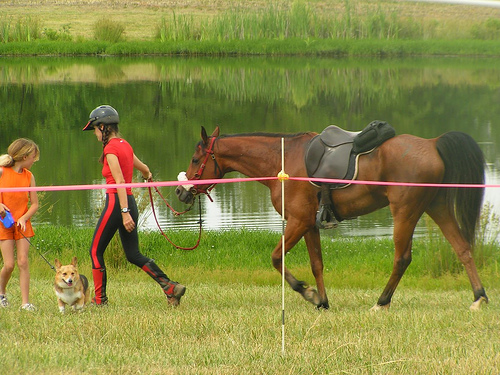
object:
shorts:
[0, 205, 36, 240]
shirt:
[99, 133, 136, 193]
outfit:
[0, 161, 37, 241]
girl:
[78, 100, 188, 305]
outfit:
[86, 137, 187, 308]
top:
[104, 134, 139, 193]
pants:
[90, 192, 171, 279]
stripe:
[85, 267, 103, 302]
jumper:
[1, 167, 35, 244]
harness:
[300, 117, 395, 194]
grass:
[183, 294, 377, 371]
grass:
[42, 315, 209, 372]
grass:
[292, 315, 484, 373]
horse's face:
[173, 143, 214, 204]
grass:
[0, 319, 154, 370]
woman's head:
[82, 101, 123, 141]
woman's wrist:
[120, 200, 132, 215]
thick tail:
[435, 127, 487, 248]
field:
[23, 314, 477, 372]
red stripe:
[90, 195, 116, 265]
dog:
[45, 254, 90, 316]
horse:
[171, 111, 492, 319]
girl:
[0, 126, 41, 311]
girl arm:
[105, 157, 137, 235]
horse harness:
[144, 175, 230, 255]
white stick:
[268, 136, 300, 353]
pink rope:
[4, 174, 497, 203]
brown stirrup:
[318, 191, 347, 228]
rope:
[192, 132, 222, 186]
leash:
[21, 226, 63, 269]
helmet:
[78, 99, 122, 132]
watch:
[117, 206, 139, 215]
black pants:
[92, 194, 486, 220]